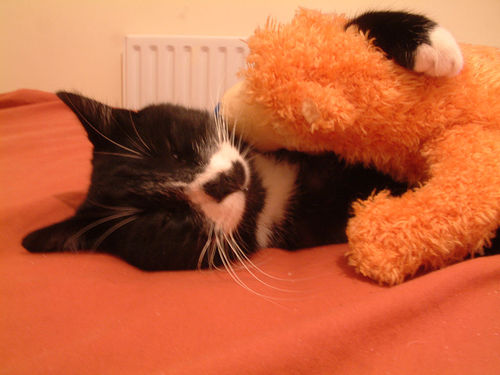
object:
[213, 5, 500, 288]
brown toy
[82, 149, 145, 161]
eyelashes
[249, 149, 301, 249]
chest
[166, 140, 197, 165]
cats eyes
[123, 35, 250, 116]
a/c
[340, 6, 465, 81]
leg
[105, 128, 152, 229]
white whiskers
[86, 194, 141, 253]
eyebrows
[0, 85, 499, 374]
blanket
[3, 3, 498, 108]
tan wall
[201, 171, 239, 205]
nose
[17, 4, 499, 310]
cat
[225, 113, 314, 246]
neck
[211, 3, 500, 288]
animal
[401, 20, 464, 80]
paw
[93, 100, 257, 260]
face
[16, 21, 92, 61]
walls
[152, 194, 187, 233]
eyes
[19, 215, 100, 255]
ear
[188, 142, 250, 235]
white markings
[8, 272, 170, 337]
red sheet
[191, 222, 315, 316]
whiskers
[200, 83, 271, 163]
whiskers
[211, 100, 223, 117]
nose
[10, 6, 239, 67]
wall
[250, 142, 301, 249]
markings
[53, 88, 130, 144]
ears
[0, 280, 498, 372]
bed